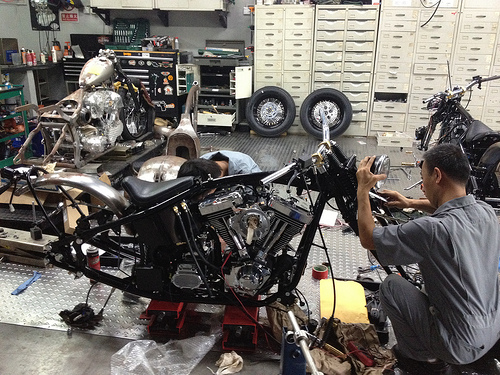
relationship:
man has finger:
[355, 144, 498, 374] [357, 153, 364, 167]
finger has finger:
[357, 153, 364, 167] [366, 153, 368, 168]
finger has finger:
[357, 153, 364, 167] [369, 151, 376, 169]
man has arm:
[355, 144, 498, 374] [377, 189, 435, 213]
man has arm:
[355, 144, 498, 374] [356, 154, 426, 251]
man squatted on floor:
[355, 144, 498, 374] [184, 280, 388, 367]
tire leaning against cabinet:
[242, 84, 295, 138] [245, 7, 392, 139]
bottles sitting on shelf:
[14, 45, 67, 68] [4, 30, 58, 147]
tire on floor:
[242, 84, 295, 138] [0, 137, 425, 373]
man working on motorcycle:
[355, 144, 498, 374] [22, 137, 409, 323]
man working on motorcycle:
[355, 144, 498, 374] [28, 113, 395, 373]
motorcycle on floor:
[408, 73, 500, 200] [27, 256, 445, 358]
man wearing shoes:
[348, 146, 484, 372] [387, 334, 473, 373]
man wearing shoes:
[355, 129, 488, 358] [389, 344, 484, 373]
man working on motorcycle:
[339, 145, 499, 373] [15, 101, 410, 365]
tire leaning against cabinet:
[298, 86, 352, 143] [248, 0, 384, 143]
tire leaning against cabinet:
[246, 84, 294, 135] [248, 0, 384, 143]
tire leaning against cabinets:
[298, 86, 352, 140] [250, 5, 484, 127]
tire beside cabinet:
[298, 86, 352, 140] [251, 0, 314, 134]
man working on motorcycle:
[355, 144, 498, 374] [15, 101, 410, 365]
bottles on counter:
[21, 50, 39, 68] [3, 62, 63, 74]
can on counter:
[24, 48, 30, 68] [3, 62, 63, 74]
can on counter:
[28, 48, 38, 70] [3, 62, 63, 74]